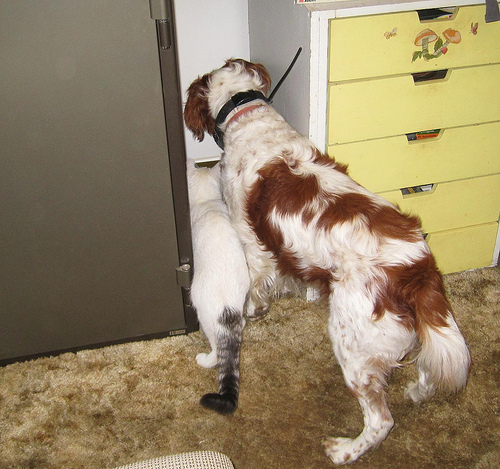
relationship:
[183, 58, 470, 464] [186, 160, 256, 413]
dog playing with cat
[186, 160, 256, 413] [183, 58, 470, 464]
cat playing with dog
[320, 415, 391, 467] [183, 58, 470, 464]
paw of dog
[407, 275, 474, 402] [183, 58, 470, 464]
tail of dog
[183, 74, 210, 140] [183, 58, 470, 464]
ear of dog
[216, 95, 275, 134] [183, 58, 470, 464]
neck of dog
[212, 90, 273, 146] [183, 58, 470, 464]
black collar of dog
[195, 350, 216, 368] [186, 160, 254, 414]
paw of cat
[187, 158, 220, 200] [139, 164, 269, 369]
head of cat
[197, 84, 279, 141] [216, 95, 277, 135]
black collar on neck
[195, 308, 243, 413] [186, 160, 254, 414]
tail of cat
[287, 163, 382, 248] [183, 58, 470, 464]
fur on back of dog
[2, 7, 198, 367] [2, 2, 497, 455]
door on room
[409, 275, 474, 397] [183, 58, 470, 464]
tail of searching dog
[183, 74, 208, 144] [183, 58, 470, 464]
ear of dog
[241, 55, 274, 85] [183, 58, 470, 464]
ear of dog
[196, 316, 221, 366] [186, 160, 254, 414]
leg of cat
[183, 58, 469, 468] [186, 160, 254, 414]
dog and cat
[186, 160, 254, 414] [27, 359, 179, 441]
cat on carpet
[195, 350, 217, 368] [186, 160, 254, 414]
paw of a cat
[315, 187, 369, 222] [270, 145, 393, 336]
spot on dog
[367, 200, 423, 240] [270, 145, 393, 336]
spot on dog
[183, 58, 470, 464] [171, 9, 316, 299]
dog in wall opening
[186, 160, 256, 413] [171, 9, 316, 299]
cat in wall opening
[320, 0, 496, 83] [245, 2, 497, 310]
drawer in chest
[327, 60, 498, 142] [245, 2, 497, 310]
drawer in chest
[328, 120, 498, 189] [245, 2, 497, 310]
drawer in chest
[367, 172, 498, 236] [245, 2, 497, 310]
drawer in chest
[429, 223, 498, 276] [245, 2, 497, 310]
drawer in chest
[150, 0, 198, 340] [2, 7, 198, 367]
bottom of door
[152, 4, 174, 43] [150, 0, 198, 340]
hinge on bottom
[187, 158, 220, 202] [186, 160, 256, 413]
head of cat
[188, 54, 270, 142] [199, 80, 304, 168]
head of dog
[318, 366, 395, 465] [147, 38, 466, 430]
leg of dog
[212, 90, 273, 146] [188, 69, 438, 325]
black collar of dog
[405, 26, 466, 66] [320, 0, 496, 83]
mushroom on drawer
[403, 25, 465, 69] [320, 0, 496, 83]
decoration on drawer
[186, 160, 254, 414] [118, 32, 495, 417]
cat and dog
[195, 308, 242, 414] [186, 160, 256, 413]
tail of a cat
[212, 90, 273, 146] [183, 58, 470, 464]
black collar on a dog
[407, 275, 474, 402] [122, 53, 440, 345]
tail of a dog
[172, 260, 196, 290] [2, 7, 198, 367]
hinge on a door